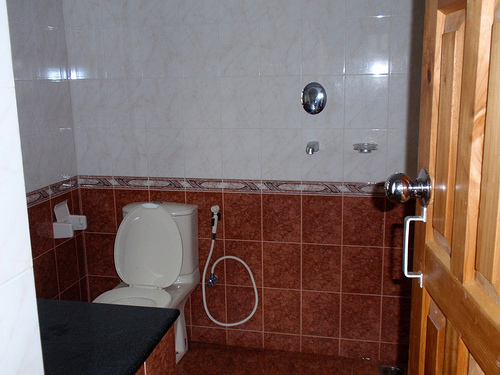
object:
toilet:
[88, 203, 206, 307]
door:
[385, 0, 500, 374]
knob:
[384, 168, 430, 217]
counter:
[44, 302, 180, 375]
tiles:
[264, 197, 298, 241]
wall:
[0, 0, 411, 188]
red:
[29, 177, 401, 362]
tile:
[303, 296, 334, 337]